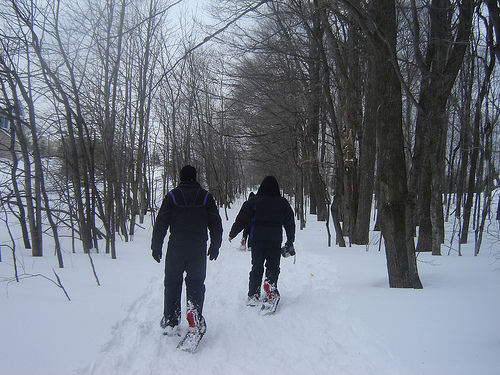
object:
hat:
[179, 165, 197, 182]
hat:
[258, 176, 281, 195]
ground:
[0, 192, 499, 374]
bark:
[413, 171, 446, 252]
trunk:
[406, 0, 482, 255]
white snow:
[5, 159, 497, 374]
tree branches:
[243, 63, 279, 126]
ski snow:
[245, 287, 285, 315]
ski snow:
[167, 290, 209, 354]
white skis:
[152, 277, 293, 359]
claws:
[170, 308, 210, 359]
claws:
[160, 316, 182, 337]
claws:
[236, 282, 263, 310]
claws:
[259, 284, 284, 319]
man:
[151, 163, 223, 353]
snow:
[0, 151, 497, 373]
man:
[228, 173, 295, 318]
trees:
[298, 0, 362, 241]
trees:
[64, 0, 168, 260]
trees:
[350, 10, 382, 245]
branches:
[131, 0, 267, 102]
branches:
[366, 16, 427, 118]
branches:
[296, 156, 338, 169]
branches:
[63, 1, 181, 55]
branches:
[3, 67, 43, 83]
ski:
[257, 281, 279, 317]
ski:
[175, 312, 208, 354]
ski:
[243, 295, 260, 306]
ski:
[160, 320, 180, 337]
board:
[176, 309, 207, 353]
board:
[259, 283, 282, 315]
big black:
[86, 166, 140, 243]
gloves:
[152, 250, 162, 263]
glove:
[207, 245, 220, 261]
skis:
[234, 242, 250, 250]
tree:
[389, 0, 477, 254]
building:
[0, 104, 30, 161]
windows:
[0, 113, 19, 135]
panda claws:
[161, 282, 279, 354]